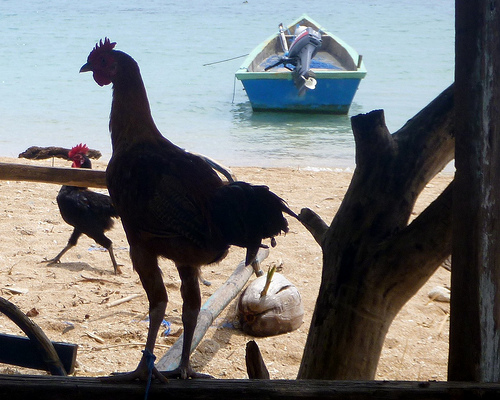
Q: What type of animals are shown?
A: Chickens.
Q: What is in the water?
A: Boat.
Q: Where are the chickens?
A: Beach.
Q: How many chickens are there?
A: Two.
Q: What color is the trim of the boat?
A: Green.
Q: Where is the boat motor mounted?
A: Back.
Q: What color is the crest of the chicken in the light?
A: Red.